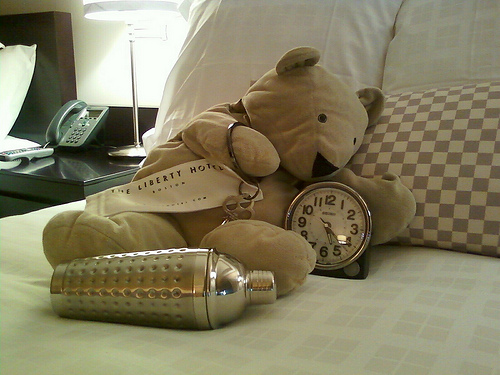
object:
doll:
[42, 45, 417, 298]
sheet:
[279, 305, 490, 361]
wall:
[70, 40, 131, 89]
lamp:
[83, 1, 180, 158]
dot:
[317, 113, 328, 124]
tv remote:
[0, 147, 55, 162]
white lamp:
[82, 2, 181, 161]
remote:
[0, 147, 54, 160]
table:
[1, 106, 152, 211]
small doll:
[40, 45, 417, 298]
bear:
[121, 36, 381, 303]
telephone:
[41, 97, 110, 150]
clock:
[282, 182, 374, 280]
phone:
[42, 99, 109, 152]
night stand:
[0, 145, 140, 219]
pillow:
[349, 85, 500, 259]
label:
[83, 158, 264, 217]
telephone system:
[44, 93, 111, 146]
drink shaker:
[49, 247, 279, 332]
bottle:
[50, 247, 277, 331]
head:
[242, 45, 385, 183]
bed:
[315, 280, 445, 354]